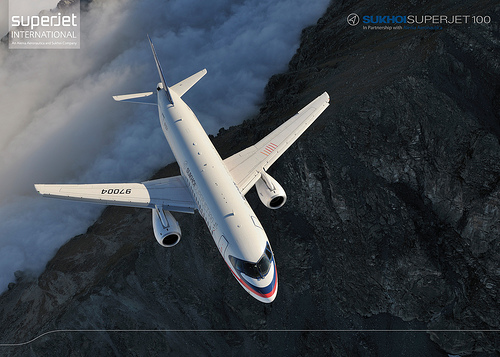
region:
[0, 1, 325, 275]
white cloud under plane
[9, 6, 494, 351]
land terrain under plane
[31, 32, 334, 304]
top view of plane in flight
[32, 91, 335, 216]
two wings of plane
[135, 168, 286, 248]
two white jet engines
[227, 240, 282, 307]
nose on front of plane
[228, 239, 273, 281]
windows of plane cockpit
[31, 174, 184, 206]
numbers on plane wing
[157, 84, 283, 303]
shadow on left side of plane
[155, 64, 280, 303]
light reflection on right side of plane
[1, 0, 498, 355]
An aerial view of a jet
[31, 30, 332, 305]
This is a passenger jet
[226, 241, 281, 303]
The jet's nose section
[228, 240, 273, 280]
The jet's cockpit windows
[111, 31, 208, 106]
The jet's tail section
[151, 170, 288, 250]
The jet's engines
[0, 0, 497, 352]
Mountains are below the jet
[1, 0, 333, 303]
The jet is above the clouds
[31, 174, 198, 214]
The jet's wing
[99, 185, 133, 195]
The jet's number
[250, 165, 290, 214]
engine on an airplane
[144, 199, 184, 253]
engine on an airplane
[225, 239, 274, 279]
windshield on an airplane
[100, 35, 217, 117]
tail of an airplane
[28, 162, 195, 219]
wing of an airplane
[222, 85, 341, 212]
wing of an airplane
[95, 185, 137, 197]
numbers on an airplane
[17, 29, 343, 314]
airplane flying over mountains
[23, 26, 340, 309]
computer generated airplane flying in the sky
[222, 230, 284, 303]
cockpit of an airplane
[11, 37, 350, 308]
airplane in flight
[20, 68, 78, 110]
white clouds in blue sky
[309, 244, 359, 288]
white clouds in blue sky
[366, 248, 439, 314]
white clouds in blue sky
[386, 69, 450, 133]
white clouds in blue sky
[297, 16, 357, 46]
white clouds in blue sky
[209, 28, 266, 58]
white clouds in blue sky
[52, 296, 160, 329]
white clouds in blue sky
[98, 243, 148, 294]
white clouds in blue sky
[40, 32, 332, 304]
a white, blue and red plane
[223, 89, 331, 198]
white wing with red stripes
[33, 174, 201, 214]
white wing with the numbers 97004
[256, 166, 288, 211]
the right engine fan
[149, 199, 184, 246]
the left engine fan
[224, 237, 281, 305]
front of airplane red, white and blue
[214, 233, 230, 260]
airplane side door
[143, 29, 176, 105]
top tail end wing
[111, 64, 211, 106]
two small tail wings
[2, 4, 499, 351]
beautiful gray mountain with white clouds